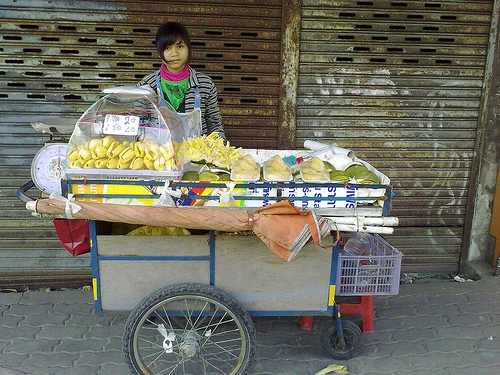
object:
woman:
[144, 20, 227, 141]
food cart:
[18, 88, 402, 374]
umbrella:
[25, 200, 400, 263]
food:
[300, 153, 332, 186]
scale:
[30, 141, 73, 200]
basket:
[341, 237, 401, 296]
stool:
[300, 275, 373, 332]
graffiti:
[401, 84, 471, 259]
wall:
[0, 0, 474, 271]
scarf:
[160, 63, 193, 111]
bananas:
[65, 144, 79, 162]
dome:
[67, 86, 185, 175]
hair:
[155, 21, 189, 63]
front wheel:
[322, 320, 363, 360]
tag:
[103, 114, 141, 136]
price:
[106, 115, 135, 126]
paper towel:
[305, 140, 355, 160]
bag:
[53, 217, 91, 256]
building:
[4, 7, 500, 276]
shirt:
[140, 70, 226, 140]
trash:
[307, 359, 356, 374]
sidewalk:
[4, 282, 499, 374]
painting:
[302, 70, 472, 250]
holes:
[13, 21, 44, 31]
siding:
[0, 4, 288, 205]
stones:
[410, 316, 459, 351]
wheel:
[126, 281, 259, 373]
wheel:
[322, 320, 364, 362]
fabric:
[160, 65, 191, 81]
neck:
[165, 65, 190, 81]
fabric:
[163, 79, 187, 108]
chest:
[154, 79, 201, 109]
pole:
[328, 213, 401, 236]